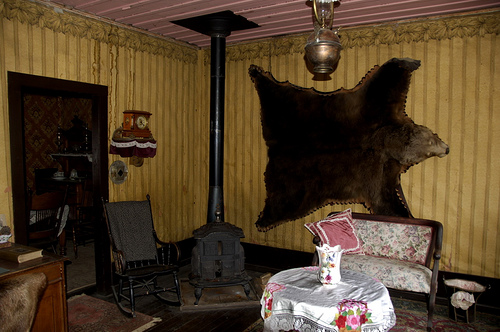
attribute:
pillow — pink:
[306, 214, 366, 255]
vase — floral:
[308, 236, 344, 290]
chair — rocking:
[97, 189, 189, 319]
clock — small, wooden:
[110, 104, 160, 145]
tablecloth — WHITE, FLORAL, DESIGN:
[278, 310, 308, 324]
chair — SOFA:
[306, 199, 444, 296]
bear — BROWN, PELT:
[238, 65, 432, 205]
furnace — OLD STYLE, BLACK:
[191, 231, 241, 279]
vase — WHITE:
[316, 251, 340, 283]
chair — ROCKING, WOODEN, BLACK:
[85, 192, 184, 302]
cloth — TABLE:
[255, 301, 292, 326]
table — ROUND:
[260, 265, 390, 330]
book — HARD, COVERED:
[8, 242, 32, 263]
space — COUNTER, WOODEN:
[38, 252, 67, 310]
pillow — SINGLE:
[315, 221, 362, 243]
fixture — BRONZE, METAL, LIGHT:
[299, 17, 345, 80]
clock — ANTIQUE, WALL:
[115, 97, 174, 167]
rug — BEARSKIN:
[248, 73, 454, 215]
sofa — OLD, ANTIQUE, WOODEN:
[343, 215, 439, 295]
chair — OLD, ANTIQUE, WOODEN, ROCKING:
[100, 194, 174, 304]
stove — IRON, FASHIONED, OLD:
[191, 225, 249, 291]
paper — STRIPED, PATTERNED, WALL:
[455, 52, 485, 152]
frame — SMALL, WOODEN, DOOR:
[65, 79, 114, 99]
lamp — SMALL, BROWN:
[116, 111, 168, 166]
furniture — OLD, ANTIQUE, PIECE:
[430, 254, 481, 322]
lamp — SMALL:
[307, 4, 343, 72]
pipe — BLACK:
[204, 29, 231, 227]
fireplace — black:
[188, 192, 259, 306]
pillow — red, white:
[300, 207, 367, 258]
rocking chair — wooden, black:
[96, 190, 185, 322]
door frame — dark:
[6, 69, 113, 296]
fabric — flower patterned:
[340, 217, 439, 295]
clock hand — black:
[141, 120, 146, 125]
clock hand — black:
[138, 116, 143, 124]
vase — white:
[313, 240, 343, 286]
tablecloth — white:
[258, 262, 397, 329]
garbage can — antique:
[442, 276, 484, 325]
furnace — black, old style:
[168, 9, 261, 307]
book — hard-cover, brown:
[1, 242, 45, 265]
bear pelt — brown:
[247, 53, 452, 233]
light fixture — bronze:
[300, 0, 343, 84]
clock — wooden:
[120, 106, 153, 141]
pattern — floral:
[365, 229, 409, 257]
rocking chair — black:
[96, 188, 190, 316]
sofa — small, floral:
[303, 206, 452, 326]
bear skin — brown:
[242, 49, 459, 258]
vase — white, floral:
[310, 240, 350, 288]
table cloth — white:
[257, 264, 404, 330]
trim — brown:
[347, 211, 440, 231]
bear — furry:
[248, 60, 423, 212]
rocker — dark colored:
[99, 202, 204, 302]